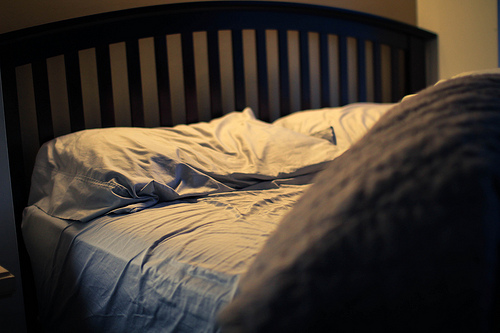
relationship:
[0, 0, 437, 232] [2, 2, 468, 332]
headboard on bed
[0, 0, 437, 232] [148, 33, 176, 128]
headboard on plank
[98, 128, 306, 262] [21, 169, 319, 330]
wrinkles on bedsheet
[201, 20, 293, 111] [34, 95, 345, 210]
wood on pillow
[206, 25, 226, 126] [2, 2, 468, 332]
bar on bed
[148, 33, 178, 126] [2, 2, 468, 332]
bar on bed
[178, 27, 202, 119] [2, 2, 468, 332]
bar on bed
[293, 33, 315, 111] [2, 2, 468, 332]
bar on bed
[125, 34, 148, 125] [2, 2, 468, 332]
bar on bed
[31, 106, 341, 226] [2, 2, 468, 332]
pillow in bed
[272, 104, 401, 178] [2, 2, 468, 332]
pillow in bed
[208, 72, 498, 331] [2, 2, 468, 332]
comforter on top of bed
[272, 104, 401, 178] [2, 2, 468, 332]
pillow on bed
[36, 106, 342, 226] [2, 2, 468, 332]
pillow on bed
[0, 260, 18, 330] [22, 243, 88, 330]
nightstand casting shadow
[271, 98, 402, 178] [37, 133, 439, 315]
pillow on bed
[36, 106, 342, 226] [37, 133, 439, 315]
pillow on bed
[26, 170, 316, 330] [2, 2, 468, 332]
bedsheet on bed